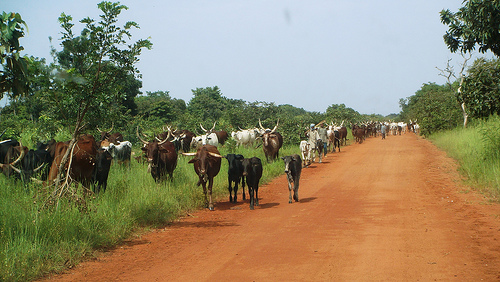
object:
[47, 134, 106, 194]
cow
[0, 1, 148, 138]
trees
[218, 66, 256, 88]
clouds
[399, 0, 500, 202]
right side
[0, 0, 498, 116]
blue sky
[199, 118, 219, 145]
cow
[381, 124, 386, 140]
man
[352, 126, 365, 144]
cattle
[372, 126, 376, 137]
cattle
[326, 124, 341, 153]
cattle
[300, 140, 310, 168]
cattle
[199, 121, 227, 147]
cattle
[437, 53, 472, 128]
tree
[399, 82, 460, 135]
tree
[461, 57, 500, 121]
tree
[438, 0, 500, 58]
tree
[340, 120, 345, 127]
large horn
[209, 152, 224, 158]
large horn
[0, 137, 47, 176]
cattle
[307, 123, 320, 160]
man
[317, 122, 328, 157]
man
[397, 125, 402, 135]
cattle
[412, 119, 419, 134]
cattle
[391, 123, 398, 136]
cattle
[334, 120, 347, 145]
cattle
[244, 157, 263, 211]
cattle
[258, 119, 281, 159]
cattle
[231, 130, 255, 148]
cattle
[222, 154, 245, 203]
cattle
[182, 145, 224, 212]
bull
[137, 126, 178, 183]
bull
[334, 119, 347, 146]
bull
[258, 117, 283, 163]
bull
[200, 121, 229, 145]
bull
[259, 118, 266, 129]
tusk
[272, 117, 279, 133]
tusk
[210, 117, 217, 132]
tusk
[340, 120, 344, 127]
tusk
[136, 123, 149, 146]
tusk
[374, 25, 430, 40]
clouds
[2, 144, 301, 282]
grass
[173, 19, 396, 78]
clouds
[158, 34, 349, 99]
clouds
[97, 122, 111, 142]
steer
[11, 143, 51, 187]
steer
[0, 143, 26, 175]
steer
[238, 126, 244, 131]
large horn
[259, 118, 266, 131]
large horn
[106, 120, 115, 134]
large horn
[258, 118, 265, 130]
horns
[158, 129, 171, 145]
horns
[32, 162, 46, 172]
horns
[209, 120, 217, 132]
horns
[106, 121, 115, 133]
horns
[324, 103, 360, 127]
tree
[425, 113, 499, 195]
grass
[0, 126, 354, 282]
field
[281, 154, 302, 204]
cattle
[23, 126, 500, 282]
road